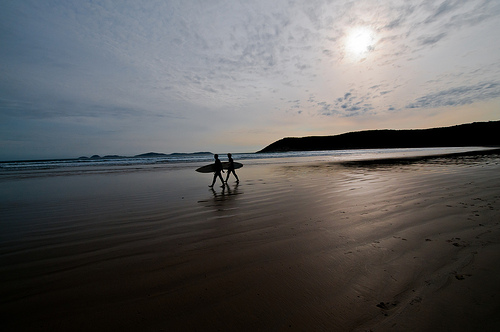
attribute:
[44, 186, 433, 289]
sand — wet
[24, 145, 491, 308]
beach — ocean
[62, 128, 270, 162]
mountains — distant, backdrop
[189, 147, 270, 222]
people — walking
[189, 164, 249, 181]
surfboard — silhoutte, edge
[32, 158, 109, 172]
waves — small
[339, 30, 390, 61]
sun — setting, shining, reflecting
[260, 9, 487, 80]
clouds — small, dark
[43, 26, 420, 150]
sky — cloudy, orange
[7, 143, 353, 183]
ocean — beach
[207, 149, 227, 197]
man — walking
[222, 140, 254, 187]
woman — walking